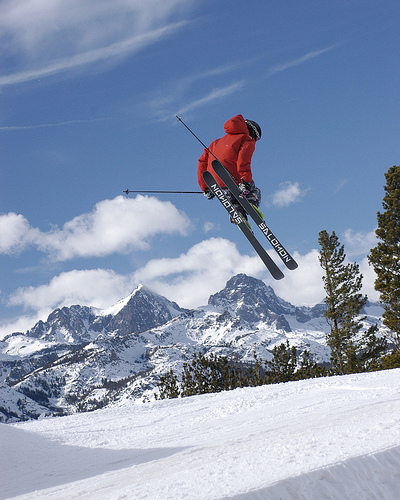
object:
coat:
[196, 115, 256, 198]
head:
[244, 119, 262, 141]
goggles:
[254, 134, 261, 141]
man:
[197, 112, 265, 224]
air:
[4, 10, 398, 332]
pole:
[122, 188, 204, 195]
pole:
[173, 113, 240, 185]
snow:
[5, 367, 399, 499]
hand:
[238, 180, 252, 199]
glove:
[237, 181, 253, 200]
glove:
[203, 188, 215, 201]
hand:
[203, 188, 215, 201]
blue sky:
[1, 1, 395, 302]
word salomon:
[258, 223, 291, 263]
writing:
[211, 184, 243, 225]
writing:
[258, 222, 291, 263]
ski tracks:
[0, 371, 400, 500]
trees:
[314, 157, 398, 372]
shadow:
[0, 422, 196, 499]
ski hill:
[2, 370, 399, 499]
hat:
[245, 119, 261, 139]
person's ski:
[202, 156, 298, 280]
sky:
[3, 2, 387, 334]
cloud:
[0, 0, 400, 335]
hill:
[0, 277, 400, 420]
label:
[257, 222, 290, 263]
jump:
[197, 113, 263, 238]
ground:
[0, 369, 399, 499]